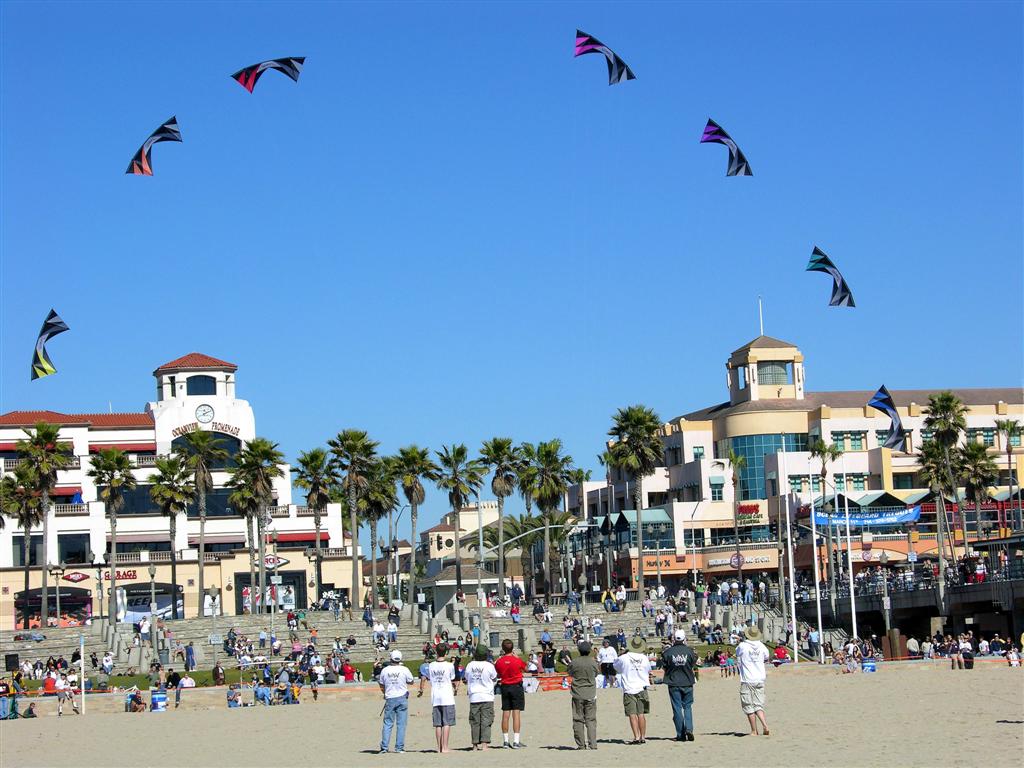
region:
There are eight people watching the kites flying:
[364, 623, 817, 735]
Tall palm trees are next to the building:
[447, 424, 597, 527]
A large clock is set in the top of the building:
[188, 398, 224, 437]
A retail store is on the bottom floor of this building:
[14, 566, 97, 630]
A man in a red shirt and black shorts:
[492, 638, 532, 750]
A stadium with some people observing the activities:
[143, 612, 358, 685]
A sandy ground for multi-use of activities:
[811, 702, 957, 764]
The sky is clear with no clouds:
[321, 110, 604, 323]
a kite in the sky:
[687, 118, 771, 194]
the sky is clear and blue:
[484, 190, 590, 260]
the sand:
[840, 721, 914, 756]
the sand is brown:
[854, 694, 937, 761]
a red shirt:
[494, 659, 524, 678]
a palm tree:
[233, 434, 288, 514]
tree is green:
[234, 446, 282, 497]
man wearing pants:
[377, 694, 406, 742]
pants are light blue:
[374, 696, 409, 742]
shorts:
[622, 690, 652, 713]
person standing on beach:
[371, 645, 409, 758]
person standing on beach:
[457, 638, 500, 751]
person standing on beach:
[492, 638, 532, 749]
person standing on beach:
[558, 638, 607, 751]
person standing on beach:
[611, 632, 660, 745]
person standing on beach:
[653, 632, 700, 741]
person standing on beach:
[730, 623, 775, 736]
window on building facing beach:
[104, 484, 173, 520]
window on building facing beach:
[183, 486, 248, 518]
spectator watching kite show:
[374, 646, 410, 749]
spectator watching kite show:
[418, 637, 457, 751]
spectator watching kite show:
[460, 637, 493, 746]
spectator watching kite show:
[490, 631, 525, 755]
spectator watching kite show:
[610, 634, 656, 742]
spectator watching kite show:
[650, 627, 699, 738]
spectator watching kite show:
[724, 618, 772, 732]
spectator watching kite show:
[277, 659, 296, 704]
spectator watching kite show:
[593, 632, 620, 684]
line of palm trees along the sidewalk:
[5, 398, 662, 620]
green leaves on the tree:
[629, 415, 645, 441]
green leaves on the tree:
[996, 453, 1006, 492]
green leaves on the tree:
[932, 431, 949, 460]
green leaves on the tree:
[470, 435, 505, 468]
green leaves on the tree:
[461, 472, 482, 501]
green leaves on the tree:
[382, 448, 425, 487]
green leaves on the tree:
[360, 431, 374, 479]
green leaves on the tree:
[241, 435, 267, 474]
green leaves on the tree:
[196, 428, 215, 461]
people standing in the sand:
[373, 650, 747, 731]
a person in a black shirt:
[660, 631, 702, 727]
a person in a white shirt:
[739, 620, 763, 728]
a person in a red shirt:
[496, 636, 532, 709]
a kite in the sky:
[119, 117, 186, 176]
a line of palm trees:
[24, 426, 655, 581]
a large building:
[603, 366, 987, 588]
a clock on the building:
[192, 402, 215, 416]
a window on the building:
[104, 481, 172, 511]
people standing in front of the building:
[53, 607, 942, 728]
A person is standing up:
[372, 646, 415, 752]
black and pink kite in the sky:
[106, 112, 189, 182]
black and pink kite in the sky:
[222, 43, 309, 105]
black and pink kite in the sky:
[564, 16, 642, 111]